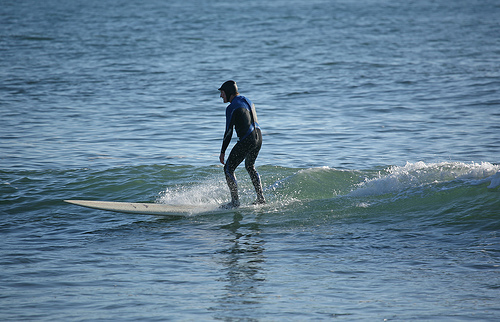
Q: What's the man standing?
A: Surfboard.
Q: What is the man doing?
A: Surfing.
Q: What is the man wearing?
A: Wetsuit.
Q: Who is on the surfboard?
A: A man.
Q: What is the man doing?
A: Riding a wave.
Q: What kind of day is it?
A: Sunny.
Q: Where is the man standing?
A: Back of the surfboard.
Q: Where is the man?
A: In the ocean.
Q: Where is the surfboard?
A: In the ocean.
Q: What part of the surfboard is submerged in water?
A: The back.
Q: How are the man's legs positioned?
A: Apart.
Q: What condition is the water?
A: Calm.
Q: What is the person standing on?
A: Surfboard.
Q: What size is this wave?
A: Small.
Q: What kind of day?
A: Clear.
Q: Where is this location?
A: Ocean.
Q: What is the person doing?
A: Surfing.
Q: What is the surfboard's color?
A: Wihte.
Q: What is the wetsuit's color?
A: Black.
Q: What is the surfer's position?
A: Standing.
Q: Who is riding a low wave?
A: Surfer.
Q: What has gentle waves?
A: The ocean.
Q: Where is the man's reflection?
A: Water.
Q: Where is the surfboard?
A: Water.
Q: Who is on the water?
A: Male surfer.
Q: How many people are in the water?
A: One.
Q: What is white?
A: Surfboard.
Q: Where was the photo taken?
A: In the ocean.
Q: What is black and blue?
A: Wetsuit.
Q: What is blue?
A: Ocean.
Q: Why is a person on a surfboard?
A: To surf.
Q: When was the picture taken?
A: Daytime.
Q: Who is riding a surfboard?
A: A man.